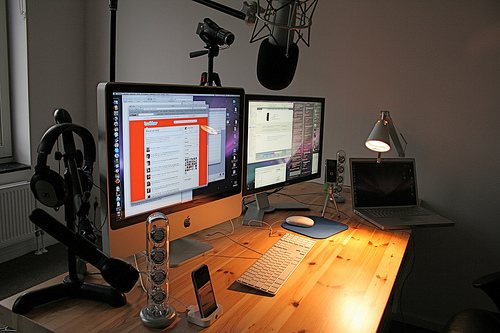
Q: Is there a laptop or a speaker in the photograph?
A: Yes, there are speakers.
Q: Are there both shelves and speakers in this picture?
A: No, there are speakers but no shelves.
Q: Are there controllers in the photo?
A: No, there are no controllers.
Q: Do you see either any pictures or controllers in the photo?
A: No, there are no controllers or pictures.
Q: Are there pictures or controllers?
A: No, there are no controllers or pictures.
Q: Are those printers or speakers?
A: Those are speakers.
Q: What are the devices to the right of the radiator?
A: The devices are speakers.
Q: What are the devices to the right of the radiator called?
A: The devices are speakers.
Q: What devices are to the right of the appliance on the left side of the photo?
A: The devices are speakers.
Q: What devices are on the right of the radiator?
A: The devices are speakers.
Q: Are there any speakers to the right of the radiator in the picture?
A: Yes, there are speakers to the right of the radiator.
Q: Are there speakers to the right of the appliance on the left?
A: Yes, there are speakers to the right of the radiator.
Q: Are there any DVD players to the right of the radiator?
A: No, there are speakers to the right of the radiator.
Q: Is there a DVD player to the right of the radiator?
A: No, there are speakers to the right of the radiator.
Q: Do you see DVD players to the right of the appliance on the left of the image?
A: No, there are speakers to the right of the radiator.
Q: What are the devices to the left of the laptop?
A: The devices are speakers.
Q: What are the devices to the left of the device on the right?
A: The devices are speakers.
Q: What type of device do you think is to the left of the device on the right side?
A: The devices are speakers.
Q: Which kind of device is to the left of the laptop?
A: The devices are speakers.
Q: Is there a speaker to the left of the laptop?
A: Yes, there are speakers to the left of the laptop.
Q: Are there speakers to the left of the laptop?
A: Yes, there are speakers to the left of the laptop.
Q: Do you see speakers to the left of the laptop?
A: Yes, there are speakers to the left of the laptop.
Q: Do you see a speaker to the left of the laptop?
A: Yes, there are speakers to the left of the laptop.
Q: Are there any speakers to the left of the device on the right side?
A: Yes, there are speakers to the left of the laptop.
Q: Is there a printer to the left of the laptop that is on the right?
A: No, there are speakers to the left of the laptop computer.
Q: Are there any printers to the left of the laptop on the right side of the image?
A: No, there are speakers to the left of the laptop computer.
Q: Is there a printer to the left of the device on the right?
A: No, there are speakers to the left of the laptop computer.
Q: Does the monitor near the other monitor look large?
A: Yes, the monitor is large.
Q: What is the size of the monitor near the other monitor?
A: The monitor is large.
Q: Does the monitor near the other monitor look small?
A: No, the monitor is large.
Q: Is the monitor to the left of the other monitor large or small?
A: The monitor is large.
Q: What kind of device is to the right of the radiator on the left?
A: The device is a monitor.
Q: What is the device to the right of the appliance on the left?
A: The device is a monitor.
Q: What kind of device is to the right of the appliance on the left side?
A: The device is a monitor.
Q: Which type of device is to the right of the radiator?
A: The device is a monitor.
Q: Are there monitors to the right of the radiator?
A: Yes, there is a monitor to the right of the radiator.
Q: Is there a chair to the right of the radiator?
A: No, there is a monitor to the right of the radiator.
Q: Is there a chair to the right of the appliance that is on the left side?
A: No, there is a monitor to the right of the radiator.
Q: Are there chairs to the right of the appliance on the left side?
A: No, there is a monitor to the right of the radiator.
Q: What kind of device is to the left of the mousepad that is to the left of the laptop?
A: The device is a monitor.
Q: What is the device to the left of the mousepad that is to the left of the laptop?
A: The device is a monitor.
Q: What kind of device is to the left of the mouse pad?
A: The device is a monitor.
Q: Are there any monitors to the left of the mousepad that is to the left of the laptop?
A: Yes, there is a monitor to the left of the mousepad.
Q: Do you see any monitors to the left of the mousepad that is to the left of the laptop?
A: Yes, there is a monitor to the left of the mousepad.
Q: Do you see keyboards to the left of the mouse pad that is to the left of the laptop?
A: No, there is a monitor to the left of the mouse pad.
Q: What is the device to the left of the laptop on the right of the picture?
A: The device is a monitor.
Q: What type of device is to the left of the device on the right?
A: The device is a monitor.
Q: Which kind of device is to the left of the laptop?
A: The device is a monitor.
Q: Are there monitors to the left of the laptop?
A: Yes, there is a monitor to the left of the laptop.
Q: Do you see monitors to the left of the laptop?
A: Yes, there is a monitor to the left of the laptop.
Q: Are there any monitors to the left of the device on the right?
A: Yes, there is a monitor to the left of the laptop.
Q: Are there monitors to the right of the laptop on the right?
A: No, the monitor is to the left of the laptop.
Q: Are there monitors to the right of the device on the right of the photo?
A: No, the monitor is to the left of the laptop.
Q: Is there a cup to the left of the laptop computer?
A: No, there is a monitor to the left of the laptop computer.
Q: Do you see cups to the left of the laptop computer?
A: No, there is a monitor to the left of the laptop computer.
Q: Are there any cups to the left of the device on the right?
A: No, there is a monitor to the left of the laptop computer.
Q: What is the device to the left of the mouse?
A: The device is a monitor.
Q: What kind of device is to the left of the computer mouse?
A: The device is a monitor.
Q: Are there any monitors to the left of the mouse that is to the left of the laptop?
A: Yes, there is a monitor to the left of the computer mouse.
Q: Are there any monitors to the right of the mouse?
A: No, the monitor is to the left of the mouse.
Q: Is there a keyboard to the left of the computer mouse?
A: No, there is a monitor to the left of the computer mouse.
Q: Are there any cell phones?
A: Yes, there is a cell phone.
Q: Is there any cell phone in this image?
A: Yes, there is a cell phone.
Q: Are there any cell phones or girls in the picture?
A: Yes, there is a cell phone.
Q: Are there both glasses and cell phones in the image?
A: No, there is a cell phone but no glasses.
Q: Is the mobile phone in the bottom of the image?
A: Yes, the mobile phone is in the bottom of the image.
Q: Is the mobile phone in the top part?
A: No, the mobile phone is in the bottom of the image.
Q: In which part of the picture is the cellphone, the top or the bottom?
A: The cellphone is in the bottom of the image.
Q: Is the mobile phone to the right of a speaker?
A: Yes, the mobile phone is to the right of a speaker.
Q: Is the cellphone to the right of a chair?
A: No, the cellphone is to the right of a speaker.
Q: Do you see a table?
A: Yes, there is a table.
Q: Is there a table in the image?
A: Yes, there is a table.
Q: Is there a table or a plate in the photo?
A: Yes, there is a table.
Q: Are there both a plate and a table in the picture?
A: No, there is a table but no plates.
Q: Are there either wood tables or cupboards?
A: Yes, there is a wood table.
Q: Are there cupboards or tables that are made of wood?
A: Yes, the table is made of wood.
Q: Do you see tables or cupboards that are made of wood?
A: Yes, the table is made of wood.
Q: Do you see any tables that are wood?
A: Yes, there is a wood table.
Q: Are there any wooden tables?
A: Yes, there is a wood table.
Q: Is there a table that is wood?
A: Yes, there is a wood table.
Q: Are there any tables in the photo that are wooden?
A: Yes, there is a table that is wooden.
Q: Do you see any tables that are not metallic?
A: Yes, there is a wooden table.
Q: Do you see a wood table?
A: Yes, there is a table that is made of wood.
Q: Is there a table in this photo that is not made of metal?
A: Yes, there is a table that is made of wood.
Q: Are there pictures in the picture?
A: No, there are no pictures.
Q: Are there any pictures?
A: No, there are no pictures.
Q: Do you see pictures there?
A: No, there are no pictures.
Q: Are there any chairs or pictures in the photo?
A: No, there are no pictures or chairs.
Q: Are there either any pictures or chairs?
A: No, there are no pictures or chairs.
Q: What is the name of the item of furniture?
A: The piece of furniture is a table.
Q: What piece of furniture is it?
A: The piece of furniture is a table.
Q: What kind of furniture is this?
A: This is a table.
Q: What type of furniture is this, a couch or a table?
A: This is a table.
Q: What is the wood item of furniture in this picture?
A: The piece of furniture is a table.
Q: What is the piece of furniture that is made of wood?
A: The piece of furniture is a table.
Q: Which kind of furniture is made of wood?
A: The furniture is a table.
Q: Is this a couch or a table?
A: This is a table.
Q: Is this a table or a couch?
A: This is a table.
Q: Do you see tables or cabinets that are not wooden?
A: No, there is a table but it is wooden.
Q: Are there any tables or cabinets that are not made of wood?
A: No, there is a table but it is made of wood.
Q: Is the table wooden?
A: Yes, the table is wooden.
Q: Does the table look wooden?
A: Yes, the table is wooden.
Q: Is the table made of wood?
A: Yes, the table is made of wood.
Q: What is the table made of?
A: The table is made of wood.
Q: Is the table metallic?
A: No, the table is wooden.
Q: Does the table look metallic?
A: No, the table is wooden.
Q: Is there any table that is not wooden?
A: No, there is a table but it is wooden.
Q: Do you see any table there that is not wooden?
A: No, there is a table but it is wooden.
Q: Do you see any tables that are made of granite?
A: No, there is a table but it is made of wood.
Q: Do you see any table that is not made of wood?
A: No, there is a table but it is made of wood.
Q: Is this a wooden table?
A: Yes, this is a wooden table.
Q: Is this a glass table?
A: No, this is a wooden table.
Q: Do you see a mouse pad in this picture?
A: Yes, there is a mouse pad.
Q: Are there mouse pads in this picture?
A: Yes, there is a mouse pad.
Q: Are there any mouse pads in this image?
A: Yes, there is a mouse pad.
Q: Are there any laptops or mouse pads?
A: Yes, there is a mouse pad.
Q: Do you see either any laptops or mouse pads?
A: Yes, there is a mouse pad.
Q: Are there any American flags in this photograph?
A: No, there are no American flags.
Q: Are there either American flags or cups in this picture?
A: No, there are no American flags or cups.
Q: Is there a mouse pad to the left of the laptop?
A: Yes, there is a mouse pad to the left of the laptop.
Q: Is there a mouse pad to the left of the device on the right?
A: Yes, there is a mouse pad to the left of the laptop.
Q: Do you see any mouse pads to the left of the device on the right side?
A: Yes, there is a mouse pad to the left of the laptop.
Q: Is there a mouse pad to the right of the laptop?
A: No, the mouse pad is to the left of the laptop.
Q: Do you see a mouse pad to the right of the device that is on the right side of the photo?
A: No, the mouse pad is to the left of the laptop.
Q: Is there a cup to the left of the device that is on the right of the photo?
A: No, there is a mouse pad to the left of the laptop computer.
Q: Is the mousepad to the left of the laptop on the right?
A: Yes, the mousepad is to the left of the laptop computer.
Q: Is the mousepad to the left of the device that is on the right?
A: Yes, the mousepad is to the left of the laptop computer.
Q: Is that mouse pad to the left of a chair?
A: No, the mouse pad is to the left of the laptop computer.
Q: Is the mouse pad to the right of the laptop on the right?
A: No, the mouse pad is to the left of the laptop.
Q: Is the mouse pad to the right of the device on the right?
A: No, the mouse pad is to the left of the laptop.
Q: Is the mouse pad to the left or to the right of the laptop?
A: The mouse pad is to the left of the laptop.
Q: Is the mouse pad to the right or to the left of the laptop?
A: The mouse pad is to the left of the laptop.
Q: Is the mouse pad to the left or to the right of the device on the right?
A: The mouse pad is to the left of the laptop.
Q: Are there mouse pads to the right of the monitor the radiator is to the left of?
A: Yes, there is a mouse pad to the right of the monitor.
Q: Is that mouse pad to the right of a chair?
A: No, the mouse pad is to the right of the monitor.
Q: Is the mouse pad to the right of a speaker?
A: Yes, the mouse pad is to the right of a speaker.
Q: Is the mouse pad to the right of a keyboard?
A: No, the mouse pad is to the right of a speaker.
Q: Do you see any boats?
A: No, there are no boats.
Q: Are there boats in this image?
A: No, there are no boats.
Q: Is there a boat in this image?
A: No, there are no boats.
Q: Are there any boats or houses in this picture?
A: No, there are no boats or houses.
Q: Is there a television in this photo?
A: No, there are no televisions.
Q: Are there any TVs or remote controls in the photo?
A: No, there are no TVs or remote controls.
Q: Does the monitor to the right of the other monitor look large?
A: Yes, the monitor is large.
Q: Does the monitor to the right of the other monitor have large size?
A: Yes, the monitor is large.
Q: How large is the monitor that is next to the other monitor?
A: The monitor is large.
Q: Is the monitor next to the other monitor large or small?
A: The monitor is large.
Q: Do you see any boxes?
A: No, there are no boxes.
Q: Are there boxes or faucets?
A: No, there are no boxes or faucets.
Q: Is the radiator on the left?
A: Yes, the radiator is on the left of the image.